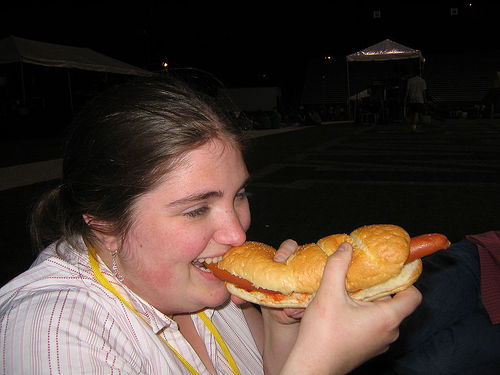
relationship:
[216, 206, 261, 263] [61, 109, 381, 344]
nose of woman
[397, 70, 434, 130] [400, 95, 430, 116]
man wears shorts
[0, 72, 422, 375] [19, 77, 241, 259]
girl has hair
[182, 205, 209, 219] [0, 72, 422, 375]
eye of girl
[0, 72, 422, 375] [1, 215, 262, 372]
girl wearing shirts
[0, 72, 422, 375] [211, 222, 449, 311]
girl holding hotdog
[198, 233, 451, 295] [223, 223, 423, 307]
hot dog longer n bun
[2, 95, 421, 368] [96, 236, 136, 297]
girl wearing earring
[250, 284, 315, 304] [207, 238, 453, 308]
ketchup on hot dog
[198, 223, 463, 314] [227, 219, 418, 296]
hot dog in a bun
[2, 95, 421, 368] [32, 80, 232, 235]
girl has hair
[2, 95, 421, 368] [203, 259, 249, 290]
girl biting long hotdog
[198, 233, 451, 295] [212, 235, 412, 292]
hot dog in a bun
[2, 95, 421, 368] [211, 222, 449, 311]
girl eating a hotdog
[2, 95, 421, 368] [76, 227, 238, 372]
girl wearing a lanyard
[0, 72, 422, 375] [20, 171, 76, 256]
girl has a pony tail